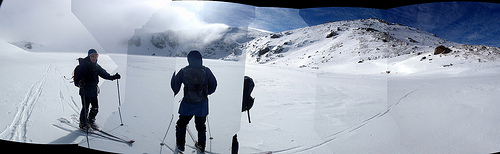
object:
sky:
[125, 0, 500, 45]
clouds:
[418, 19, 431, 21]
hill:
[219, 16, 500, 77]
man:
[72, 48, 121, 133]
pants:
[79, 95, 99, 129]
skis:
[55, 116, 132, 144]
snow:
[0, 49, 499, 154]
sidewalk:
[0, 41, 500, 154]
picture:
[0, 0, 500, 154]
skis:
[70, 113, 135, 144]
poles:
[114, 72, 125, 126]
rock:
[433, 44, 453, 55]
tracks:
[391, 87, 424, 106]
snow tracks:
[0, 111, 22, 141]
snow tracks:
[277, 144, 306, 152]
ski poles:
[80, 87, 94, 149]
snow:
[245, 15, 466, 48]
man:
[169, 49, 218, 154]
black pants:
[174, 114, 208, 152]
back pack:
[241, 75, 257, 124]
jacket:
[170, 66, 218, 117]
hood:
[186, 50, 203, 66]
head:
[187, 50, 203, 66]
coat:
[72, 57, 116, 96]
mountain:
[124, 17, 500, 76]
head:
[87, 48, 99, 63]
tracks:
[56, 89, 67, 102]